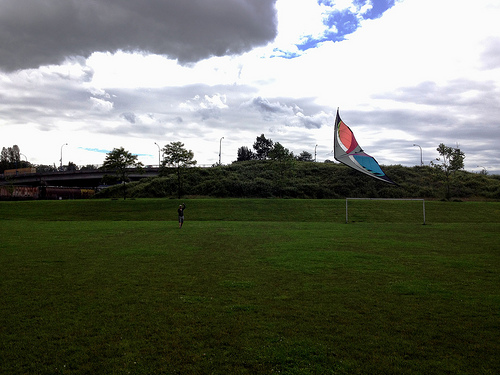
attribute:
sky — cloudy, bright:
[0, 1, 500, 174]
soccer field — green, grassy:
[0, 219, 498, 374]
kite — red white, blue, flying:
[333, 107, 403, 187]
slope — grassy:
[0, 197, 500, 222]